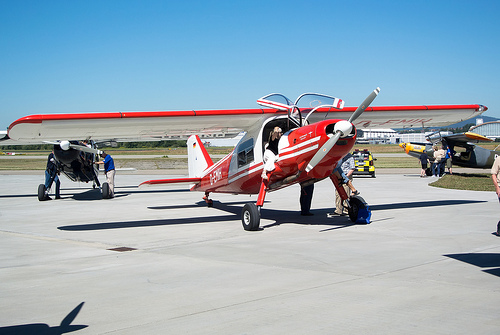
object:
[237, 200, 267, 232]
wheel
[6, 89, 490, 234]
airplane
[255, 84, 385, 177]
propeller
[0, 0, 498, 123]
sky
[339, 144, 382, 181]
car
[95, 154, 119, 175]
shirt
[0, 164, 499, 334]
area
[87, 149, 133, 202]
man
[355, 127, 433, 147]
building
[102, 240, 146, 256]
grate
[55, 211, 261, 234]
shadow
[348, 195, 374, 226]
wheel piece